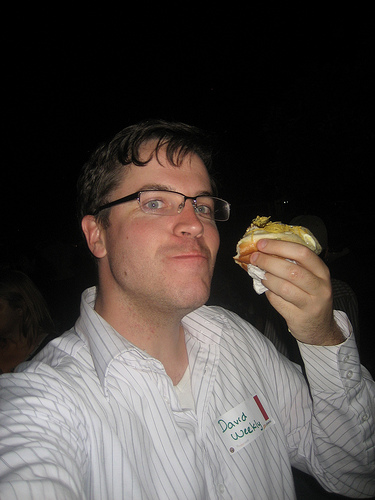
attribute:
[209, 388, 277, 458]
name tag — White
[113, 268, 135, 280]
mole — Brown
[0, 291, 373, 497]
shirt — white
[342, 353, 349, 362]
button — White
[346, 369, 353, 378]
button — White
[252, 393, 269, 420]
stripe — Red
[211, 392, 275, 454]
name tag — White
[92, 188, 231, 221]
eye glasses — Black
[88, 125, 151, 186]
hair — short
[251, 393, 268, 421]
line — red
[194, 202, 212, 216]
eye — blue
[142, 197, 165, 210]
eye — blue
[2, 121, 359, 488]
man — dress